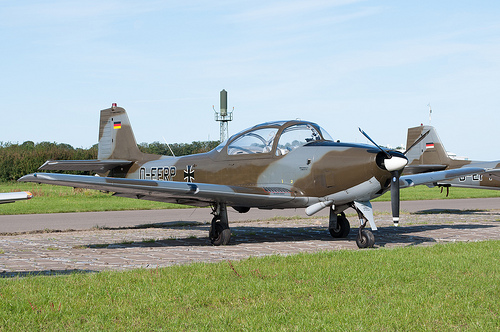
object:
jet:
[16, 102, 487, 249]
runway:
[0, 197, 500, 235]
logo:
[139, 165, 196, 183]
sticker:
[113, 121, 122, 130]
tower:
[212, 88, 234, 142]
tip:
[404, 158, 408, 165]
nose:
[375, 149, 409, 173]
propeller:
[390, 173, 400, 229]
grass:
[0, 241, 500, 332]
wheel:
[209, 221, 231, 246]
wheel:
[328, 215, 350, 238]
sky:
[0, 0, 500, 163]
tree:
[0, 140, 19, 183]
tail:
[97, 103, 143, 160]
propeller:
[358, 127, 392, 158]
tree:
[173, 143, 192, 157]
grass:
[0, 183, 198, 214]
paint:
[255, 146, 354, 197]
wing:
[17, 172, 309, 207]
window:
[226, 133, 267, 156]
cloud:
[221, 0, 499, 66]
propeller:
[402, 128, 432, 155]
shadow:
[83, 220, 500, 249]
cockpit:
[207, 117, 334, 161]